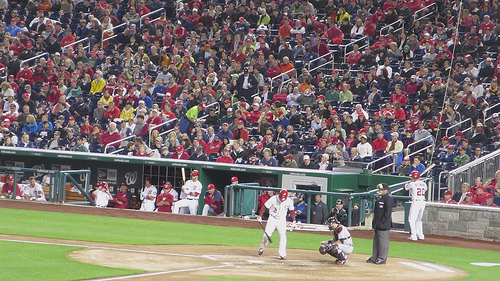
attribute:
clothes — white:
[262, 201, 289, 258]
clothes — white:
[404, 182, 428, 239]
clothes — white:
[173, 181, 200, 215]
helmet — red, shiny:
[280, 192, 289, 204]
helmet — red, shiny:
[410, 170, 421, 181]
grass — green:
[5, 225, 234, 276]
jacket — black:
[375, 197, 391, 231]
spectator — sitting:
[103, 102, 118, 117]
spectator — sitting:
[218, 124, 230, 143]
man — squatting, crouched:
[322, 217, 355, 264]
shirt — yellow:
[122, 111, 132, 121]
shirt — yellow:
[88, 80, 104, 93]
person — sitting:
[168, 140, 191, 160]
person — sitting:
[262, 148, 280, 164]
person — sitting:
[437, 190, 454, 202]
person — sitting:
[340, 84, 355, 101]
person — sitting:
[327, 22, 339, 45]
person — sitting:
[49, 131, 66, 151]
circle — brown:
[70, 236, 459, 280]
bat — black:
[258, 225, 275, 245]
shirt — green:
[326, 93, 337, 102]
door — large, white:
[279, 177, 328, 222]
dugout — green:
[0, 150, 387, 226]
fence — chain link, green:
[2, 166, 89, 208]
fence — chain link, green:
[229, 185, 376, 227]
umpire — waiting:
[372, 185, 398, 265]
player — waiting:
[404, 167, 433, 243]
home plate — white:
[247, 258, 264, 265]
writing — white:
[378, 201, 386, 210]